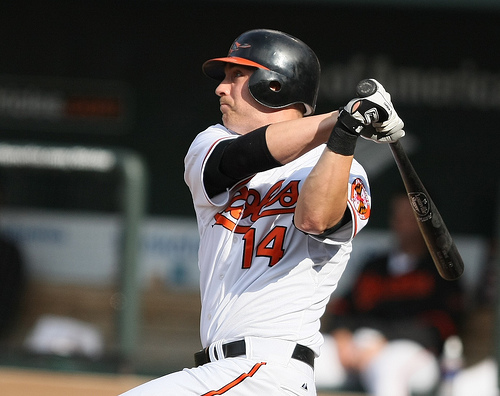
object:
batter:
[116, 28, 408, 394]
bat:
[356, 79, 466, 283]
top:
[182, 123, 372, 347]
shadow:
[201, 167, 373, 296]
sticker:
[410, 190, 432, 220]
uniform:
[119, 124, 372, 394]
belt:
[195, 339, 313, 367]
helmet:
[202, 28, 321, 118]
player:
[116, 28, 409, 393]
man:
[313, 195, 462, 394]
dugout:
[0, 0, 495, 394]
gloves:
[327, 79, 406, 157]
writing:
[407, 189, 432, 222]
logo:
[408, 190, 430, 219]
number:
[240, 225, 290, 268]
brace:
[204, 124, 284, 199]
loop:
[209, 343, 224, 362]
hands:
[339, 79, 406, 144]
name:
[322, 52, 499, 110]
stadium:
[0, 1, 498, 236]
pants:
[117, 337, 316, 395]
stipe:
[200, 360, 269, 394]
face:
[215, 66, 248, 132]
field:
[4, 363, 164, 394]